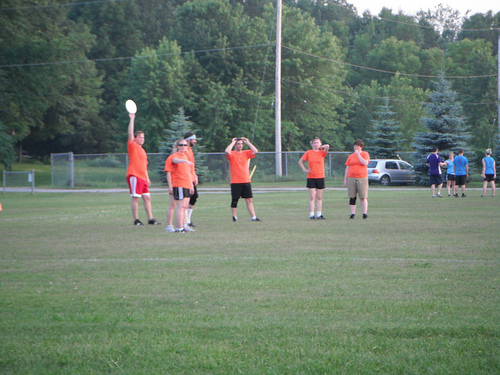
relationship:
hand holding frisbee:
[129, 113, 136, 120] [123, 98, 136, 114]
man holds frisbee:
[127, 113, 161, 225] [122, 97, 139, 115]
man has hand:
[127, 113, 161, 225] [129, 113, 136, 120]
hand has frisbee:
[129, 113, 136, 120] [122, 97, 139, 115]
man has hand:
[127, 113, 161, 225] [125, 108, 137, 121]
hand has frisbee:
[125, 108, 137, 121] [124, 92, 137, 116]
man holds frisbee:
[127, 113, 161, 225] [123, 101, 137, 116]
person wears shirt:
[343, 139, 371, 220] [346, 149, 370, 179]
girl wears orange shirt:
[297, 137, 329, 220] [301, 148, 327, 179]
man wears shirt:
[224, 136, 260, 221] [221, 151, 256, 186]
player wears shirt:
[157, 135, 201, 229] [170, 154, 191, 187]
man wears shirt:
[127, 113, 161, 225] [123, 143, 148, 183]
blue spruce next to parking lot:
[409, 64, 479, 188] [310, 129, 462, 199]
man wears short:
[126, 174, 149, 198] [122, 99, 160, 226]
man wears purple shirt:
[423, 141, 445, 197] [426, 153, 443, 173]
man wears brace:
[222, 134, 263, 223] [231, 191, 239, 209]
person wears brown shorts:
[341, 136, 373, 220] [343, 175, 369, 201]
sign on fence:
[26, 168, 33, 181] [0, 150, 350, 189]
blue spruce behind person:
[417, 64, 467, 184] [425, 141, 445, 195]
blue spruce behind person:
[417, 64, 467, 184] [437, 149, 452, 199]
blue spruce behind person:
[417, 64, 467, 184] [449, 149, 470, 200]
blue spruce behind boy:
[417, 64, 467, 184] [481, 148, 497, 197]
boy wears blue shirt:
[477, 148, 494, 196] [482, 152, 494, 176]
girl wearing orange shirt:
[298, 136, 330, 223] [299, 149, 326, 178]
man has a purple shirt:
[425, 147, 446, 198] [426, 153, 442, 176]